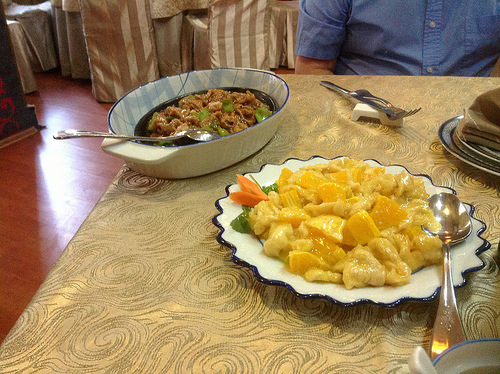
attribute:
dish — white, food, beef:
[201, 210, 255, 265]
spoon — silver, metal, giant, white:
[413, 174, 497, 254]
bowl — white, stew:
[78, 139, 243, 204]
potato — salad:
[350, 201, 396, 259]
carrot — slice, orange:
[218, 179, 264, 221]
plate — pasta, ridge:
[220, 241, 279, 289]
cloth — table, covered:
[73, 240, 216, 371]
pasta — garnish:
[257, 174, 366, 251]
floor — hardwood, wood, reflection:
[5, 196, 78, 251]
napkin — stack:
[456, 97, 494, 167]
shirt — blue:
[337, 9, 485, 73]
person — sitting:
[280, 3, 498, 86]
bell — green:
[242, 99, 274, 134]